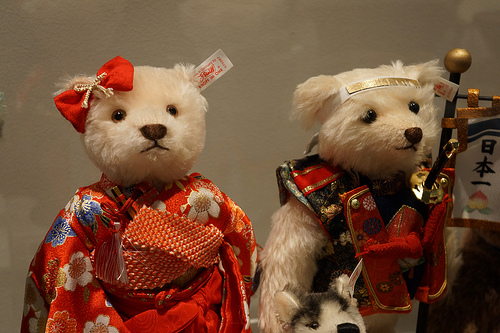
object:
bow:
[51, 54, 137, 134]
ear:
[50, 71, 101, 101]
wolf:
[274, 262, 372, 333]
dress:
[19, 173, 257, 333]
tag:
[189, 46, 235, 94]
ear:
[174, 60, 200, 83]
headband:
[333, 75, 429, 106]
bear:
[252, 59, 465, 332]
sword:
[406, 140, 461, 218]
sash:
[100, 265, 237, 333]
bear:
[16, 45, 266, 333]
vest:
[273, 153, 424, 312]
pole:
[419, 70, 466, 224]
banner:
[437, 86, 500, 233]